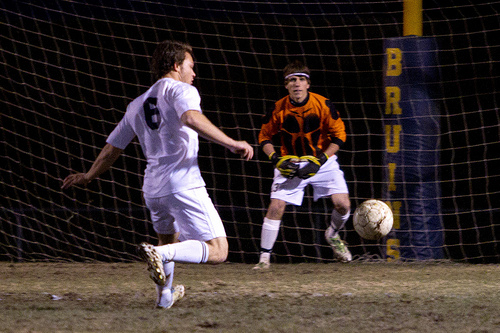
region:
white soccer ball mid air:
[350, 198, 403, 248]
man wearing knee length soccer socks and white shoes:
[138, 238, 213, 308]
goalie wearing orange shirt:
[256, 90, 353, 175]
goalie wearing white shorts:
[268, 160, 346, 210]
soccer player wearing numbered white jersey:
[103, 81, 206, 206]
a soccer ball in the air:
[356, 196, 392, 238]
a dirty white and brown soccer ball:
[353, 200, 392, 239]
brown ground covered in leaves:
[0, 262, 499, 331]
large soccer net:
[0, 0, 496, 260]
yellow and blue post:
[379, 2, 449, 258]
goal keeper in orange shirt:
[255, 60, 360, 267]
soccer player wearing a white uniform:
[59, 40, 254, 307]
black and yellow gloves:
[272, 149, 325, 179]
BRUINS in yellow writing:
[383, 45, 405, 260]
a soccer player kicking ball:
[59, 41, 396, 311]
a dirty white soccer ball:
[351, 200, 393, 242]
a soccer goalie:
[248, 66, 351, 273]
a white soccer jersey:
[105, 80, 204, 197]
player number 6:
[141, 94, 161, 129]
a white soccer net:
[0, 0, 499, 263]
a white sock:
[160, 240, 208, 264]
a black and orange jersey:
[258, 90, 345, 158]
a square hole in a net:
[423, 228, 443, 248]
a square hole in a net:
[388, 231, 410, 243]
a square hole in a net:
[457, 224, 478, 254]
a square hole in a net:
[475, 210, 486, 230]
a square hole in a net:
[453, 159, 466, 184]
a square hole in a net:
[421, 165, 438, 183]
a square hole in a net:
[371, 164, 383, 181]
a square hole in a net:
[356, 135, 373, 154]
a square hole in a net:
[52, 200, 60, 217]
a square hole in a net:
[64, 122, 76, 140]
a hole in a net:
[32, 208, 44, 227]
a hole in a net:
[229, 173, 249, 192]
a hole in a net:
[233, 205, 258, 230]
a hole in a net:
[236, 222, 246, 237]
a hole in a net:
[242, 238, 255, 250]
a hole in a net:
[243, 252, 258, 259]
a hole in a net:
[284, 223, 301, 241]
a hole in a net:
[286, 240, 298, 254]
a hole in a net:
[316, 228, 326, 242]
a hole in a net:
[319, 243, 351, 265]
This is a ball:
[350, 190, 402, 245]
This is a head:
[146, 33, 213, 93]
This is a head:
[279, 57, 315, 109]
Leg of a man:
[250, 167, 297, 277]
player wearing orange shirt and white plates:
[252, 61, 353, 272]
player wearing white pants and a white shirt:
[61, 40, 255, 310]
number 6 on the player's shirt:
[141, 95, 161, 130]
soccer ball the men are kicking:
[352, 195, 394, 241]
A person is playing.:
[61, 36, 241, 306]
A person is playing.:
[251, 62, 361, 287]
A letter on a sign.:
[385, 199, 401, 234]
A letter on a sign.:
[383, 161, 398, 194]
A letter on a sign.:
[383, 122, 403, 152]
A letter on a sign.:
[385, 85, 407, 119]